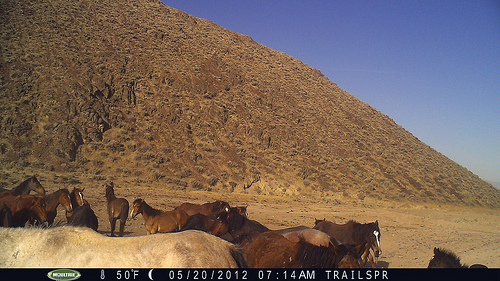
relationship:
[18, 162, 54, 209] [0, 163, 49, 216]
head on horse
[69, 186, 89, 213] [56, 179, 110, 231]
head on horse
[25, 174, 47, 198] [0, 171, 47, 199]
head on horse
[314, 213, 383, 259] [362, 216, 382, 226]
horse has ears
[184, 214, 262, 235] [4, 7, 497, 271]
horse in desert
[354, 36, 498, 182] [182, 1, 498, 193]
clouds in sky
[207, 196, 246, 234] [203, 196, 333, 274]
head of horse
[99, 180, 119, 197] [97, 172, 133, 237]
head of horse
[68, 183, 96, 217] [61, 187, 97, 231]
horse head of horse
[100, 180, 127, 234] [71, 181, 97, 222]
horse of horse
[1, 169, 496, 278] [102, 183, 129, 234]
group containing horse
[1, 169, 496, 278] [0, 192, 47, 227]
group containing horse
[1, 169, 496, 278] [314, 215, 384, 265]
group containing horse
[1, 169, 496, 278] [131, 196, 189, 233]
group containing horse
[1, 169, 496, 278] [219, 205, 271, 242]
group containing horse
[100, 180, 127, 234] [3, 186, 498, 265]
horse in desert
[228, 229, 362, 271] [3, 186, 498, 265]
horse in desert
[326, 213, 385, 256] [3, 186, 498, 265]
horse in desert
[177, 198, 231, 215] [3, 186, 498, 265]
horse in desert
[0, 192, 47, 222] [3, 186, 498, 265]
horse in desert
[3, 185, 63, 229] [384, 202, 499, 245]
horse in desert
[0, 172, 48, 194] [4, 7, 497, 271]
brown horse in desert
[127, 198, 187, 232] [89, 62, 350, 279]
horse in desert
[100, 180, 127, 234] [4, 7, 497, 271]
horse in desert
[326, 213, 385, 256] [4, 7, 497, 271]
horse in desert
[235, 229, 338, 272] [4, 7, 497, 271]
horse in desert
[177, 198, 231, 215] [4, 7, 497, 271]
horse in desert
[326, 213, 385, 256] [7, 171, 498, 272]
horse in desert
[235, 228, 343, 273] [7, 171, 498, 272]
horse in desert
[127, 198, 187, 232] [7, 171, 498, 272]
horse in desert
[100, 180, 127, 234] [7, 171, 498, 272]
horse in desert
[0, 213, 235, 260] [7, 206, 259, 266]
back on horse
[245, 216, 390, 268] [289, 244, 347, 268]
horse's with mane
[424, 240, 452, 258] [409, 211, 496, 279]
ear of horse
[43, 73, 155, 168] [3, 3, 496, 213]
outcrop on hillside